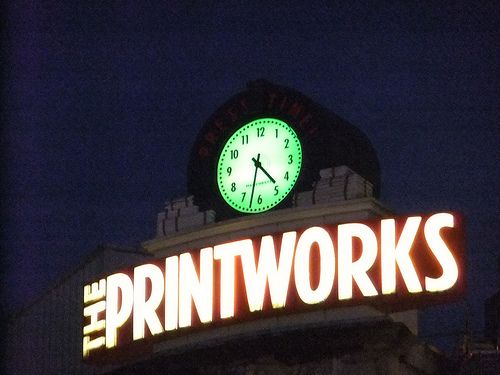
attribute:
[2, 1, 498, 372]
sky — dark, blue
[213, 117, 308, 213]
clock — glowing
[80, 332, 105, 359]
letter — sideways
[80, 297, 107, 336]
letter — sideways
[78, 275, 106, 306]
letter — sideways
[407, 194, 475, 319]
light — part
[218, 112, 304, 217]
clock — glowing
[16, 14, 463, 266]
sky —  dark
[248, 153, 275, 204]
hands — black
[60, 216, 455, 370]
lights — white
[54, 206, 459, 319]
glow — red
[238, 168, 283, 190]
letters — black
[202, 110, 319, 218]
clock — glowing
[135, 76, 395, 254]
top — concrete